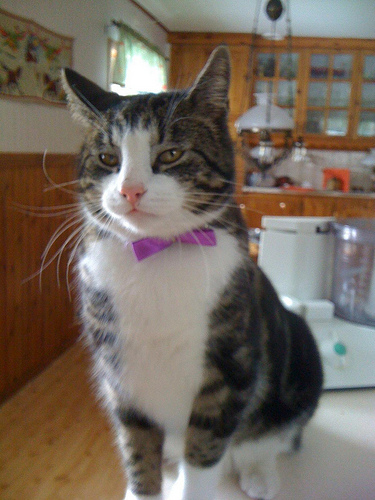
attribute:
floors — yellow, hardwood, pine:
[1, 332, 123, 498]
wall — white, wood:
[2, 0, 170, 409]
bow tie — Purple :
[129, 225, 216, 260]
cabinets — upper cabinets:
[243, 30, 372, 150]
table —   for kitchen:
[2, 143, 260, 498]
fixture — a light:
[224, 101, 310, 181]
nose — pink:
[121, 185, 147, 205]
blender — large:
[254, 215, 372, 391]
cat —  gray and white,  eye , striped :
[17, 41, 335, 499]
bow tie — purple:
[133, 227, 215, 260]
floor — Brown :
[26, 340, 108, 495]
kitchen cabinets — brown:
[237, 191, 372, 238]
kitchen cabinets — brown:
[169, 31, 373, 150]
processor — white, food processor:
[256, 204, 357, 343]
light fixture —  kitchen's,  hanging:
[231, 0, 304, 171]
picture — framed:
[0, 7, 75, 107]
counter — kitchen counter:
[121, 386, 373, 498]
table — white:
[120, 390, 374, 498]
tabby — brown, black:
[23, 48, 359, 498]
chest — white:
[83, 234, 239, 425]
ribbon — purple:
[125, 225, 218, 261]